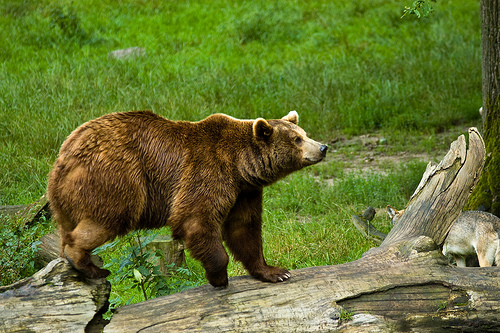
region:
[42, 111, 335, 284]
brown furry bear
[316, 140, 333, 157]
black nose on a bear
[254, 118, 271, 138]
ear on the bear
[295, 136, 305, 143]
right eye on the bear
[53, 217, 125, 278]
back right leg of the bear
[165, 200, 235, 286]
front right leg of the bear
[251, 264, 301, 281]
front left foot of the bear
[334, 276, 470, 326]
hole in the fallen down tree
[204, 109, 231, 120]
hump on the bear's back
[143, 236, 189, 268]
tree stump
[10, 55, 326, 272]
brown bear on the tree trunk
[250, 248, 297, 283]
paw of the bear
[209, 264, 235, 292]
paw of the bear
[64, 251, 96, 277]
paw of the bear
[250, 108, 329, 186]
head of the bear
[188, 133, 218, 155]
fur of the bear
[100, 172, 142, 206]
fur of the bera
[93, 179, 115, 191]
fur of the bear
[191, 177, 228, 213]
fur of the bear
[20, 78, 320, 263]
brown bear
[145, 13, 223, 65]
green leaves on brown treesgreen leaves on brown trees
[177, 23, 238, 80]
green leaves on brown trees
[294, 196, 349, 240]
green leaves on brown trees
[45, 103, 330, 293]
Grizzly bear on a log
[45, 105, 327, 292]
grizzly bear is large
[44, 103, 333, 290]
grizzly bear is brown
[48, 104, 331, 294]
grizzly bear is fuzzy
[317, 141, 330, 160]
grizzly bear has a black nose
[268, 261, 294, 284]
grizzly bear has sharp claws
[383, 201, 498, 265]
coyote near tree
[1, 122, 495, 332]
a fallen dead log in a field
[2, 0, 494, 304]
grass is bright green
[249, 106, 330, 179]
a grizzle bear head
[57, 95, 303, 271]
a large bear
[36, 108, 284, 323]
a bear on a log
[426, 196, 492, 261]
an animal behind the log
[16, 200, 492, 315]
a large wooden log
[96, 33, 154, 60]
a rock in the grass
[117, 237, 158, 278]
leaves on a branch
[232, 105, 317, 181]
the face of the bear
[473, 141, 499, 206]
moss on the tree trunk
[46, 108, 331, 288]
the bear is brown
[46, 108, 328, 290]
the bear is fluffy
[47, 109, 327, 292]
the bear is on all fours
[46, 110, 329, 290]
the bear has claws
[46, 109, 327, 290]
the bear has a black nose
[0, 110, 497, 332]
the bear is on the large log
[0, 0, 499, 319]
the bright green grass around the bear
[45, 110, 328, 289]
the bear has ears